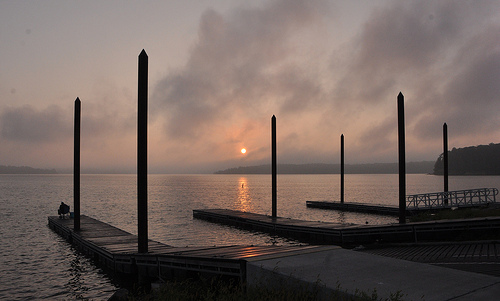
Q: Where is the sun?
A: In the sky.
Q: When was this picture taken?
A: Sunset.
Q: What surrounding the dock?
A: Water.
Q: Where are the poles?
A: On the dock.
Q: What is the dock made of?
A: Wood.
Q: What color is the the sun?
A: Orange.